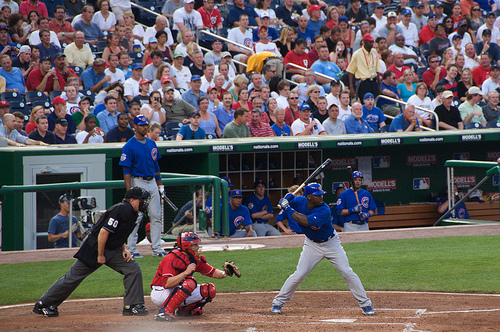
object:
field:
[1, 222, 500, 330]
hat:
[304, 182, 328, 198]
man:
[359, 92, 387, 130]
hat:
[363, 92, 375, 101]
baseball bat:
[277, 156, 335, 210]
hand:
[278, 198, 290, 211]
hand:
[283, 193, 296, 202]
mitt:
[222, 260, 243, 279]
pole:
[372, 93, 439, 131]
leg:
[33, 256, 103, 317]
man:
[346, 32, 384, 109]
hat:
[361, 32, 377, 41]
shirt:
[345, 45, 381, 83]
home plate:
[318, 317, 356, 323]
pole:
[0, 173, 234, 243]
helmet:
[176, 232, 201, 253]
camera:
[71, 196, 99, 235]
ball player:
[268, 183, 379, 315]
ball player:
[148, 230, 241, 322]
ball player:
[29, 184, 151, 319]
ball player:
[118, 114, 169, 260]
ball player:
[335, 170, 377, 233]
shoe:
[357, 304, 377, 317]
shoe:
[269, 302, 285, 317]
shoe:
[150, 309, 183, 324]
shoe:
[122, 303, 151, 316]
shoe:
[31, 300, 61, 316]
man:
[47, 191, 84, 250]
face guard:
[138, 188, 152, 213]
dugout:
[111, 132, 500, 244]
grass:
[0, 233, 500, 311]